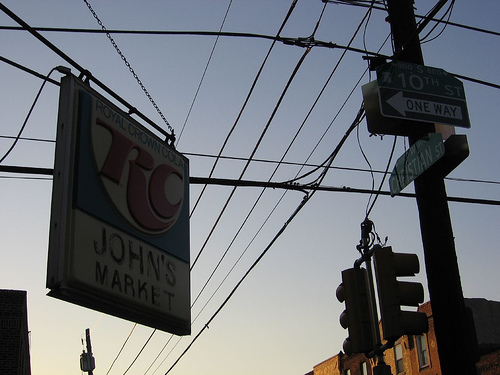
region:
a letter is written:
[91, 226, 108, 258]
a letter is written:
[107, 232, 126, 265]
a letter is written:
[130, 238, 149, 275]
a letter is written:
[145, 250, 168, 289]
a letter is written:
[161, 252, 179, 285]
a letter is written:
[89, 256, 114, 287]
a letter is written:
[110, 269, 130, 295]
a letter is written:
[121, 272, 138, 299]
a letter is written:
[132, 275, 154, 306]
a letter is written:
[148, 282, 165, 310]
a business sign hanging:
[41, 64, 211, 334]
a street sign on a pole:
[364, 48, 474, 94]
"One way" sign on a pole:
[358, 74, 479, 124]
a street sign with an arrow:
[382, 85, 486, 135]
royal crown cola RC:
[30, 70, 235, 342]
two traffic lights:
[307, 202, 437, 366]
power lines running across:
[119, 6, 367, 263]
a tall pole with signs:
[369, 6, 498, 348]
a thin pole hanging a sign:
[4, 6, 220, 361]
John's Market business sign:
[58, 212, 205, 324]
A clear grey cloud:
[226, 318, 309, 359]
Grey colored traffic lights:
[336, 265, 380, 352]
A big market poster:
[52, 57, 227, 321]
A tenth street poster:
[364, 58, 478, 142]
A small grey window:
[414, 337, 432, 367]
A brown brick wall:
[318, 348, 341, 373]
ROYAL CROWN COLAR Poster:
[96, 102, 199, 174]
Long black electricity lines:
[262, 98, 316, 176]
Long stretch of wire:
[105, 38, 152, 85]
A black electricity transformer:
[69, 322, 99, 374]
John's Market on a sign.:
[82, 215, 194, 310]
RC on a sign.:
[91, 97, 193, 217]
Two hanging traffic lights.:
[306, 240, 434, 365]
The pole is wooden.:
[398, 200, 478, 362]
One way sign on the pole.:
[376, 85, 473, 132]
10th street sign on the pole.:
[373, 54, 465, 98]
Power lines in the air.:
[196, 28, 325, 237]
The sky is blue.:
[249, 281, 332, 351]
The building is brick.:
[323, 307, 498, 373]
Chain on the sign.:
[93, 3, 185, 125]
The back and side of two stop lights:
[336, 236, 435, 359]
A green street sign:
[374, 125, 467, 186]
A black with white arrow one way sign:
[353, 90, 476, 119]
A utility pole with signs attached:
[364, 5, 488, 266]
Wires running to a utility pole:
[207, 10, 421, 243]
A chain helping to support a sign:
[100, 41, 183, 139]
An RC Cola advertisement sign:
[62, 108, 203, 336]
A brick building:
[308, 289, 473, 368]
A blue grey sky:
[137, 25, 338, 152]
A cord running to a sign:
[4, 61, 96, 162]